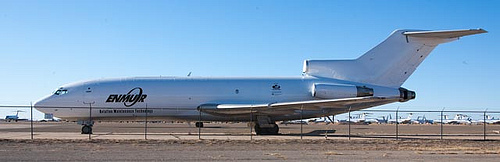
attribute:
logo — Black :
[98, 82, 151, 107]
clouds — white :
[16, 25, 103, 70]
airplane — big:
[30, 22, 495, 149]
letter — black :
[96, 101, 161, 122]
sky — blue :
[1, 1, 499, 114]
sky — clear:
[3, 6, 498, 123]